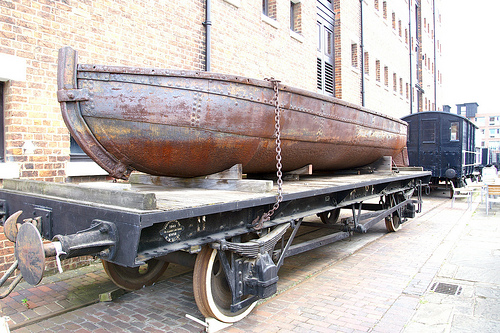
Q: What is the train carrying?
A: A boat.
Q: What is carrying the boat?
A: A train.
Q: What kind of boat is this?
A: A rowboat.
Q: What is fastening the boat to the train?
A: Chains.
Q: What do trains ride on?
A: Tracks.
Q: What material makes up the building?
A: Bricks.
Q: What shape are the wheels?
A: Round.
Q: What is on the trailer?
A: A boat.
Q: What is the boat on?
A: A train car.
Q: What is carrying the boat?
A: A long iron flatbed.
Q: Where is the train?
A: On it's track.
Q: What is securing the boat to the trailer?
A: A chain.